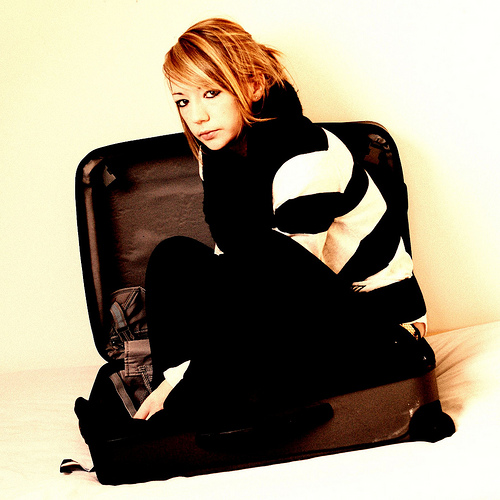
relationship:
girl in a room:
[132, 15, 440, 436] [1, 2, 500, 499]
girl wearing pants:
[132, 15, 440, 436] [145, 228, 422, 400]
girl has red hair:
[132, 15, 440, 436] [165, 17, 299, 163]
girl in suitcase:
[132, 15, 440, 436] [64, 125, 461, 484]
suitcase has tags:
[64, 125, 461, 484] [60, 456, 96, 476]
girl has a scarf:
[132, 15, 440, 436] [203, 80, 299, 251]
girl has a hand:
[132, 15, 440, 436] [133, 378, 175, 420]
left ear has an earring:
[250, 69, 266, 102] [254, 96, 259, 99]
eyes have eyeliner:
[176, 89, 224, 109] [174, 88, 220, 109]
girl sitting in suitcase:
[132, 15, 440, 436] [64, 125, 461, 484]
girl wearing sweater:
[132, 15, 440, 436] [196, 117, 426, 336]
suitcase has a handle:
[64, 125, 461, 484] [196, 403, 336, 450]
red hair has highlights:
[165, 17, 299, 163] [183, 32, 272, 123]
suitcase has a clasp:
[64, 125, 461, 484] [60, 456, 96, 476]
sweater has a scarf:
[196, 117, 426, 336] [203, 80, 299, 251]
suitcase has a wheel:
[64, 125, 461, 484] [423, 412, 455, 444]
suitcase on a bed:
[64, 125, 461, 484] [0, 319, 499, 499]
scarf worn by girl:
[203, 80, 299, 251] [132, 15, 440, 436]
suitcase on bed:
[64, 125, 461, 484] [0, 319, 499, 499]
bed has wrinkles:
[0, 319, 499, 499] [436, 333, 488, 415]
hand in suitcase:
[133, 378, 175, 420] [64, 125, 461, 484]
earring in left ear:
[254, 96, 259, 99] [250, 69, 266, 102]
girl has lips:
[132, 15, 440, 436] [198, 129, 224, 140]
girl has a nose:
[132, 15, 440, 436] [191, 93, 209, 125]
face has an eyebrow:
[169, 76, 242, 150] [173, 91, 186, 97]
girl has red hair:
[132, 15, 440, 436] [161, 17, 302, 166]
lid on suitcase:
[74, 118, 411, 360] [64, 125, 461, 484]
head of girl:
[169, 18, 266, 150] [103, 15, 427, 395]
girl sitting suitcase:
[103, 15, 427, 395] [64, 125, 461, 484]